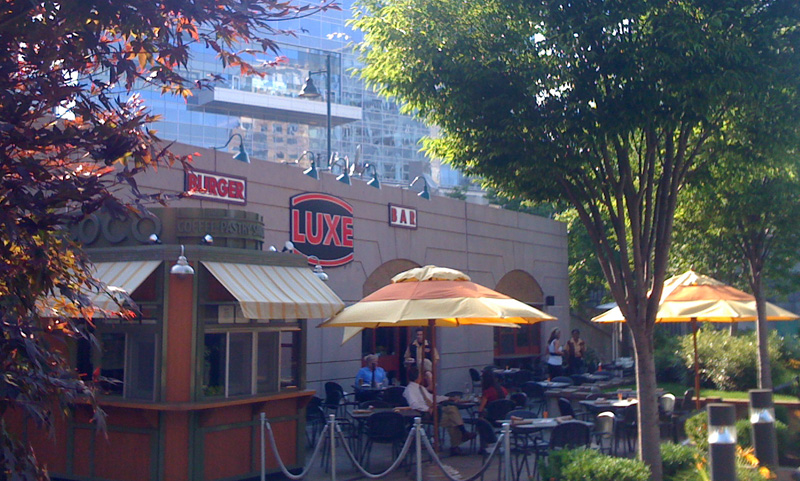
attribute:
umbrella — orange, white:
[591, 247, 796, 325]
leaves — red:
[8, 9, 210, 414]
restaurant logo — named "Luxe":
[278, 185, 358, 268]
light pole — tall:
[294, 40, 350, 178]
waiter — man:
[393, 326, 437, 378]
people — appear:
[543, 322, 589, 381]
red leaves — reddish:
[0, 5, 341, 417]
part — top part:
[366, 21, 771, 197]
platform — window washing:
[184, 82, 364, 125]